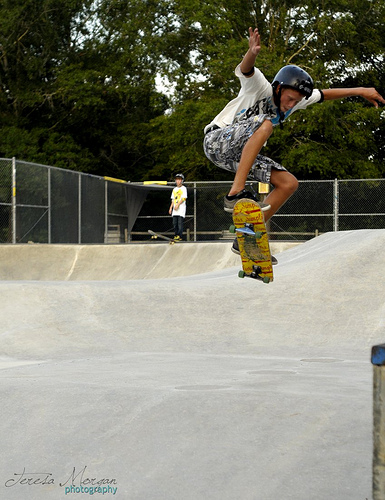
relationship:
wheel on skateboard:
[228, 224, 238, 232] [230, 197, 277, 284]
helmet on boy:
[272, 65, 314, 101] [201, 26, 385, 267]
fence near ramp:
[1, 153, 382, 244] [228, 228, 382, 296]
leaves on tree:
[53, 69, 80, 98] [0, 1, 383, 181]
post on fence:
[331, 175, 339, 232] [1, 153, 382, 244]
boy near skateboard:
[201, 26, 385, 267] [230, 197, 277, 284]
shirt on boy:
[203, 63, 323, 135] [201, 26, 385, 267]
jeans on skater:
[170, 216, 184, 241] [170, 173, 189, 243]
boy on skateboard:
[201, 26, 383, 265] [230, 197, 277, 284]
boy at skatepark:
[201, 26, 383, 265] [2, 228, 383, 500]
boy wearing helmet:
[201, 26, 383, 265] [272, 65, 314, 101]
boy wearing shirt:
[201, 26, 383, 265] [203, 63, 323, 135]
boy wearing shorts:
[201, 26, 383, 265] [203, 116, 288, 189]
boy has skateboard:
[201, 26, 383, 265] [230, 197, 277, 284]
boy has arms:
[201, 26, 383, 265] [228, 24, 383, 109]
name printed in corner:
[3, 462, 121, 498] [2, 457, 130, 497]